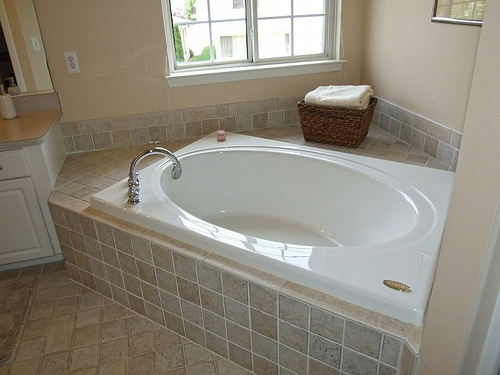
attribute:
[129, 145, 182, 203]
faucet — silver, metal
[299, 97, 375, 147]
basket — brown, wicker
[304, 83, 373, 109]
towel — folded, white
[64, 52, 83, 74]
electrical socket — white, here, reflected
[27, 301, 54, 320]
tile — brown, tan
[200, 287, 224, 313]
tile — brown, tan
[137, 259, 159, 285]
tile — brown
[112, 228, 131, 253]
tile — tan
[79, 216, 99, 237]
tile — brown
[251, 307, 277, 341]
tile — brown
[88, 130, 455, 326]
bathtub — rectangular, white, in the corner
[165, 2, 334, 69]
window — white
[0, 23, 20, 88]
mirror — silver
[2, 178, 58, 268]
compartment — here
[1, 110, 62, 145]
counter — here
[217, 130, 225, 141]
bottle — pink